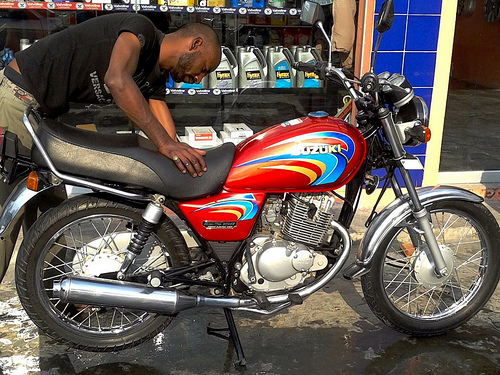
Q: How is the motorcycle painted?
A: Red.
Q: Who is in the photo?
A: A man.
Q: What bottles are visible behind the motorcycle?
A: Oil.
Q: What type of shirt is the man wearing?
A: Tee shirt.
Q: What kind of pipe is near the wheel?
A: Exhaust pipe.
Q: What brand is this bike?
A: Suzuki.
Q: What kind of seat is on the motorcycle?
A: Leather seat.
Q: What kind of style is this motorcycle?
A: Cruiser motorcycle style.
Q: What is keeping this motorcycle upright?
A: Kickstand.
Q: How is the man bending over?
A: By holding onto the bike.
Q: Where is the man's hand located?
A: On top of the motorcycle seat.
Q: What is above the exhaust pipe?
A: Motorcycle suspension.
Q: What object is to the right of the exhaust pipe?
A: Right foot brake.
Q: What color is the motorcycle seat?
A: The motorcycle seat is black.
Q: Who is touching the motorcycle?
A: The man in the black shirt.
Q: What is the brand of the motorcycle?
A: The brand is Suzuki.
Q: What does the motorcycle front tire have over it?
A: It has a silver fender over it.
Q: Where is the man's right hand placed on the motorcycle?
A: It is placed on the seat.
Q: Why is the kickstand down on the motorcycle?
A: It is down to keep it from falling.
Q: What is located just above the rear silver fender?
A: A turn signal lamp is located just above the silver fender.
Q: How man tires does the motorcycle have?
A: The motorcycle has two tires.